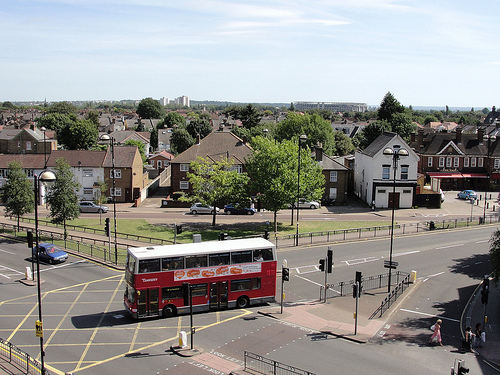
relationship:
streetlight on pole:
[282, 265, 292, 283] [280, 263, 286, 317]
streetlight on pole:
[104, 216, 110, 239] [107, 219, 112, 262]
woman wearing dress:
[425, 317, 447, 349] [431, 322, 444, 343]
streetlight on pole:
[180, 281, 191, 309] [188, 283, 195, 351]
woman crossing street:
[425, 317, 447, 349] [1, 222, 499, 374]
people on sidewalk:
[461, 319, 490, 354] [466, 269, 499, 369]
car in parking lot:
[455, 188, 478, 203] [437, 186, 499, 221]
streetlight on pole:
[328, 247, 337, 275] [324, 256, 330, 302]